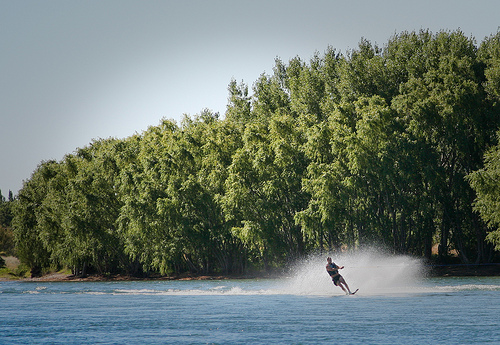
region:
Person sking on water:
[272, 250, 404, 307]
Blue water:
[25, 276, 215, 334]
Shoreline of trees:
[17, 91, 477, 266]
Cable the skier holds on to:
[344, 258, 499, 270]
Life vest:
[318, 259, 340, 276]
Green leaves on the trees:
[16, 113, 226, 246]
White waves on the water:
[57, 270, 292, 307]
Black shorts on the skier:
[327, 273, 349, 288]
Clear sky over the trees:
[2, 76, 257, 168]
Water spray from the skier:
[282, 243, 456, 298]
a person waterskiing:
[326, 252, 361, 297]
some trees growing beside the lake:
[3, 27, 498, 273]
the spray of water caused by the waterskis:
[296, 244, 425, 295]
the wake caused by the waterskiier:
[4, 285, 328, 295]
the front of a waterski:
[351, 287, 361, 295]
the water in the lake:
[2, 277, 499, 344]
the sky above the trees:
[1, 1, 498, 197]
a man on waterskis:
[324, 255, 359, 297]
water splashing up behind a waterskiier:
[294, 242, 427, 295]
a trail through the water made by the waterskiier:
[6, 286, 337, 293]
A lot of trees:
[0, 21, 499, 284]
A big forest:
[2, 17, 497, 284]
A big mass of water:
[5, 249, 493, 343]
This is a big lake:
[0, 265, 499, 342]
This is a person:
[312, 244, 364, 301]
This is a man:
[322, 249, 362, 303]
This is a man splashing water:
[282, 244, 433, 312]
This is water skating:
[316, 256, 369, 299]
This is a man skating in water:
[290, 241, 393, 308]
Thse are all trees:
[7, 27, 492, 272]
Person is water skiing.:
[316, 251, 366, 305]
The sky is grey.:
[16, 8, 148, 95]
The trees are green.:
[121, 115, 455, 229]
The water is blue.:
[56, 307, 176, 343]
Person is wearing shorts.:
[323, 272, 355, 283]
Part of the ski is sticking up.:
[333, 285, 376, 305]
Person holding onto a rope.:
[342, 246, 499, 277]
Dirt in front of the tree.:
[34, 263, 80, 283]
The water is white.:
[126, 282, 285, 299]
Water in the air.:
[280, 252, 415, 288]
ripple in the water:
[209, 296, 246, 314]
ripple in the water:
[196, 309, 226, 324]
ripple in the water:
[351, 321, 393, 338]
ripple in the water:
[137, 317, 172, 333]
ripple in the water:
[128, 317, 156, 337]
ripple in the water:
[417, 279, 466, 297]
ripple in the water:
[418, 322, 458, 339]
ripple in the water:
[90, 295, 112, 308]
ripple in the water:
[196, 282, 228, 296]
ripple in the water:
[297, 307, 321, 317]